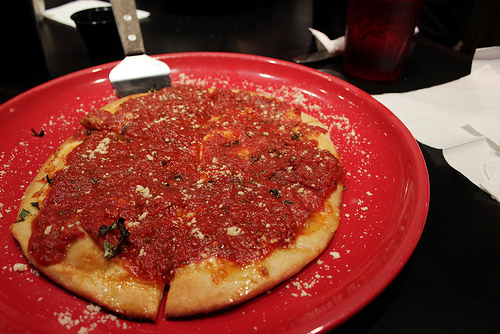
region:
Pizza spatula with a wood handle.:
[95, 0, 177, 107]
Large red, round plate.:
[3, 37, 443, 329]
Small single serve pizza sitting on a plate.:
[11, 78, 343, 323]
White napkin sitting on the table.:
[362, 44, 498, 202]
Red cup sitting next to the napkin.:
[329, 3, 421, 83]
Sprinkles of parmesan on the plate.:
[353, 133, 388, 216]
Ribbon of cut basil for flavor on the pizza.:
[98, 212, 133, 265]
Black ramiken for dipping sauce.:
[65, 4, 123, 39]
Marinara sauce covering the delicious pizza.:
[211, 195, 268, 252]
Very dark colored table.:
[434, 235, 498, 310]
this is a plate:
[353, 147, 405, 214]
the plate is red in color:
[352, 156, 405, 238]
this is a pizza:
[11, 85, 343, 320]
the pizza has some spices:
[60, 166, 223, 232]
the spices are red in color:
[143, 178, 205, 215]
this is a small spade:
[108, 1, 175, 88]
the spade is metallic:
[122, 66, 149, 81]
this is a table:
[433, 256, 499, 319]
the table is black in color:
[405, 277, 475, 319]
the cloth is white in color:
[463, 155, 481, 167]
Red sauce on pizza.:
[133, 107, 226, 215]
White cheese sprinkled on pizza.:
[126, 170, 265, 300]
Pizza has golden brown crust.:
[123, 240, 249, 315]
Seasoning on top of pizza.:
[4, 187, 109, 238]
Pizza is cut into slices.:
[72, 92, 337, 322]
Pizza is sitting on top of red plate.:
[243, 63, 427, 316]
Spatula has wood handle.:
[93, 8, 195, 67]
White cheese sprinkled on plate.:
[37, 295, 82, 320]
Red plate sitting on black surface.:
[313, 173, 439, 319]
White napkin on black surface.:
[417, 59, 459, 250]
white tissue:
[390, 85, 498, 206]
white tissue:
[381, 55, 465, 135]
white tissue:
[394, 81, 445, 209]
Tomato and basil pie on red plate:
[11, 79, 353, 332]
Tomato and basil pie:
[10, 78, 361, 319]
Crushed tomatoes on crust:
[1, 71, 361, 311]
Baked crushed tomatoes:
[20, 73, 353, 315]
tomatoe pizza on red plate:
[16, 77, 375, 309]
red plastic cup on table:
[332, 0, 439, 103]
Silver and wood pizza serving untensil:
[82, 1, 243, 158]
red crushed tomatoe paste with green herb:
[91, 196, 161, 263]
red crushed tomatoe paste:
[83, 173, 128, 211]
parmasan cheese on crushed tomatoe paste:
[118, 168, 161, 231]